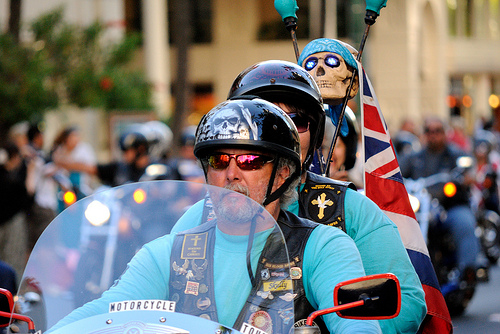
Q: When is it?
A: Day time.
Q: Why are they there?
A: Parade.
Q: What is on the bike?
A: People.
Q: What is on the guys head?
A: Helmet.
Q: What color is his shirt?
A: Blue.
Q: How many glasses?
A: 2.